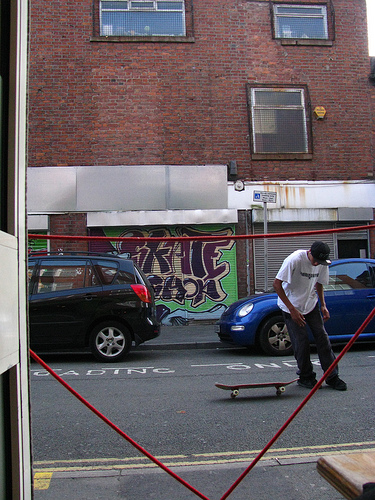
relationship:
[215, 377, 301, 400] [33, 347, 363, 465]
skateboard in street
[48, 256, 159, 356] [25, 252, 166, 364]
back of vehicle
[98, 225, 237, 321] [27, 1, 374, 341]
graffiti on building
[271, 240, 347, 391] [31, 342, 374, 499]
boy skateboarding in street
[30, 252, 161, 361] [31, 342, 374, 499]
car parked along street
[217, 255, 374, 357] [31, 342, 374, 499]
car parked along street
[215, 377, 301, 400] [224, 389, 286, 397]
skateboard on wheels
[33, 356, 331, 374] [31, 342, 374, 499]
lettering painted on street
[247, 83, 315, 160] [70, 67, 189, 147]
window on building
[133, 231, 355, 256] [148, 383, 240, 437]
rope along street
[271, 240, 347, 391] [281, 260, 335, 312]
boy wearing shirt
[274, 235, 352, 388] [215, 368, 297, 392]
boy with skateboard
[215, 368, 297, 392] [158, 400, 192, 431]
skateboard in street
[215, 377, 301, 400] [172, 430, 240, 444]
skateboard on ground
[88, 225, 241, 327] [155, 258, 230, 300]
graffiti on gate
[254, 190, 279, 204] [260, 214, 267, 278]
marks on pole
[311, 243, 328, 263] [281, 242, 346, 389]
cap of boy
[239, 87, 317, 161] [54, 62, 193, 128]
window of building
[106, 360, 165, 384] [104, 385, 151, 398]
letters on street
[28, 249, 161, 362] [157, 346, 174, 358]
car parked on street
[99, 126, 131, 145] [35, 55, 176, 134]
wall of a building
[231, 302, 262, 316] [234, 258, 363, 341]
headlight of a car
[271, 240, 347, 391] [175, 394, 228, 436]
boy in the street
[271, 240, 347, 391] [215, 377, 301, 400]
boy looking down at skateboard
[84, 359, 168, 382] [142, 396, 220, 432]
lettering on the street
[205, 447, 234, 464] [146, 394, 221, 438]
lines on the street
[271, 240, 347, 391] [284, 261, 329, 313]
boy wearing shirt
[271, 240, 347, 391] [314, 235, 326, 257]
boy wearing cap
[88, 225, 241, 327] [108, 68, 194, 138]
graffiti on the building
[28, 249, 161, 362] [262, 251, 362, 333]
car parked in front car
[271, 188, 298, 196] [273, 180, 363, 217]
marks on trim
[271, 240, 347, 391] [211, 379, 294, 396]
boy riding a skateboard